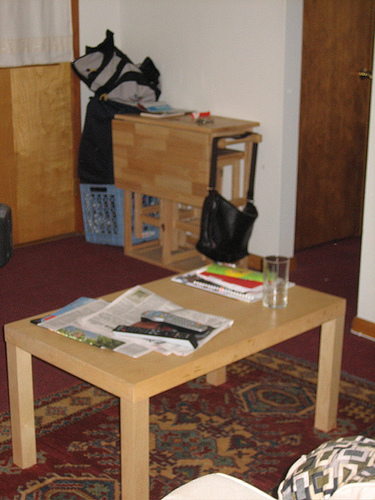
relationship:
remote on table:
[136, 307, 211, 338] [2, 261, 350, 499]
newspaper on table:
[36, 285, 236, 362] [2, 261, 350, 499]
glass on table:
[260, 249, 294, 313] [2, 261, 350, 499]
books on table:
[169, 258, 298, 307] [2, 261, 350, 499]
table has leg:
[2, 261, 350, 499] [308, 303, 347, 437]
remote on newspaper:
[136, 307, 211, 338] [36, 285, 236, 362]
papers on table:
[36, 285, 236, 362] [2, 261, 350, 499]